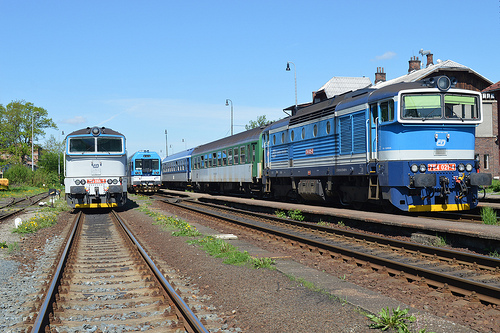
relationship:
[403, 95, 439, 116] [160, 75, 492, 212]
window in front of train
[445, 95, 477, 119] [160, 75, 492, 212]
window in front of train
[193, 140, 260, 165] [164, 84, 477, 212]
windows on side of train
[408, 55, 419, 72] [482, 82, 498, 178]
chimney on building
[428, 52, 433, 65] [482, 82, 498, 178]
chimney on building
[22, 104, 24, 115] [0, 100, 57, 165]
leaves on tree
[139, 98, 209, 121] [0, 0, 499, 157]
cloud in a blue sky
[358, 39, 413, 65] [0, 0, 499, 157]
clouds in a blue sky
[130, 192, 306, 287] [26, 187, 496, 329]
grass in between tracks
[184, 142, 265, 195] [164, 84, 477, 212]
windows on side of train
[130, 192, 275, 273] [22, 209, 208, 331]
grass growing on train tracks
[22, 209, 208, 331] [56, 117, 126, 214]
train tracks for train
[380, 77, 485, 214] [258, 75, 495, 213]
front of train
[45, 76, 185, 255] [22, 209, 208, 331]
train on train tracks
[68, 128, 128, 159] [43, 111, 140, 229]
windows on front of train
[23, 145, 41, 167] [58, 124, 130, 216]
building next to train